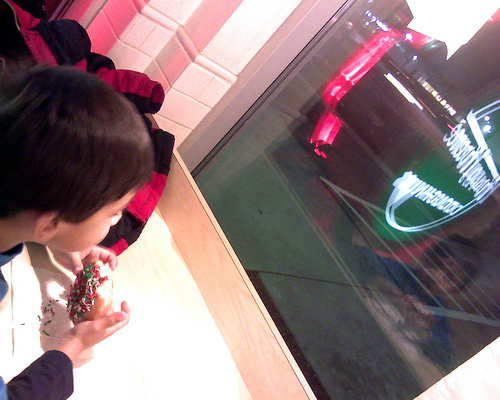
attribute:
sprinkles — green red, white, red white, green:
[25, 295, 59, 341]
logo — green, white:
[382, 86, 497, 244]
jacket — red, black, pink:
[4, 1, 173, 255]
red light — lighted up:
[307, 22, 436, 160]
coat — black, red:
[28, 28, 157, 168]